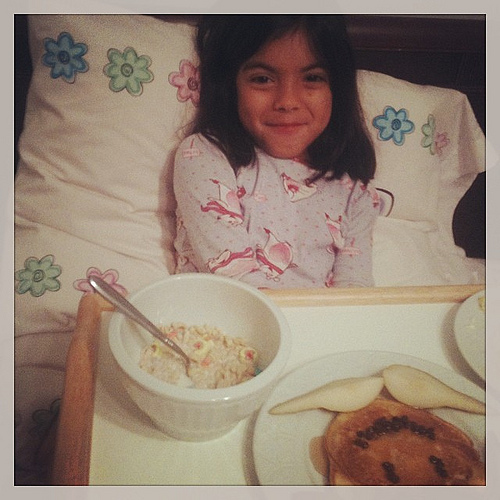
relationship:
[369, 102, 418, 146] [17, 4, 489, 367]
flower on pillow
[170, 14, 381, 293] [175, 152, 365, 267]
girl wearing pajamas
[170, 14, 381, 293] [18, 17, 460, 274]
girl leaning against pillow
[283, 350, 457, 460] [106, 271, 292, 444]
slices on bowl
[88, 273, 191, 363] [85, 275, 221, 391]
handle of spoon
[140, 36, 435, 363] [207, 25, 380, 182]
girl with hair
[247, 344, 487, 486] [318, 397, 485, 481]
plate with pancake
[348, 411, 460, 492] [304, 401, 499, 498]
happy face on pancake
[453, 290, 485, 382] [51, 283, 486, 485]
plate on tray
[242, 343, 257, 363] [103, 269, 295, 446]
marshmallow in bowl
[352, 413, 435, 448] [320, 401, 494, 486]
chocolate chips on pancakes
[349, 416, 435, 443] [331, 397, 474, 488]
chips are on pancake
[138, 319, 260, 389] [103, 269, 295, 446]
oatmeal in bowl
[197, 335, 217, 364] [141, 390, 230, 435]
fruit in bowl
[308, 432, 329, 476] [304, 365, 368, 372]
syrup on plate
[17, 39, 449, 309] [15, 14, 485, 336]
flowers are on pillow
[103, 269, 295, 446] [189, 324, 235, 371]
bowl of oatmeal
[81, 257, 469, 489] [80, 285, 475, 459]
tray of breakfast items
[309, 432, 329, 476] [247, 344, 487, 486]
syrup on plate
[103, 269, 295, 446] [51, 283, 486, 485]
bowl on tray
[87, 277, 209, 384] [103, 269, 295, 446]
spoon in bowl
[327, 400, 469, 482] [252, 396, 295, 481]
pancakes on plate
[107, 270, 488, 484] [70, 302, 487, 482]
food on a tray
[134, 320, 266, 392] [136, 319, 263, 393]
cereal in milk